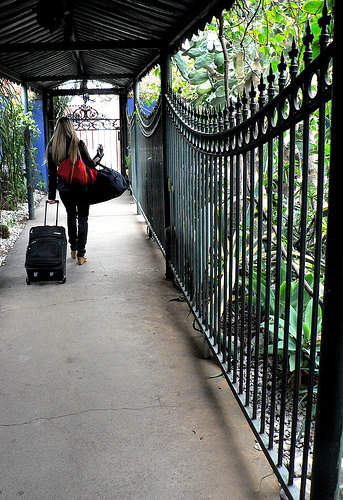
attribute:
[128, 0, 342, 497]
gate — black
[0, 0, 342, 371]
leaves — green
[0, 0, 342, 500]
poles — black, present, blue, wrought iron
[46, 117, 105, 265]
woman — lady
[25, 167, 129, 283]
luggage — black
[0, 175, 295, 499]
cement — clean, grey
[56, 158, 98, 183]
bag — red, carried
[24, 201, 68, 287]
luggage — black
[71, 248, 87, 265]
shoes — tall heels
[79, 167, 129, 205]
bag — black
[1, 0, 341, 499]
gated area — long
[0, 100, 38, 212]
plants — small